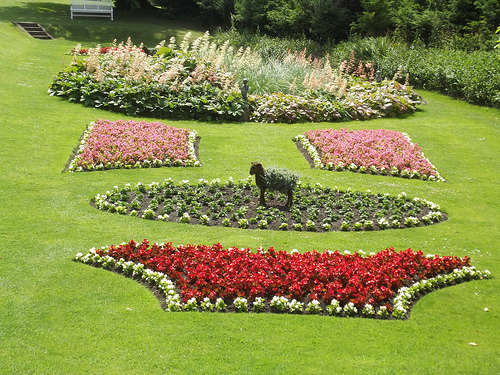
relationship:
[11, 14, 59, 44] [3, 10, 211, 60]
stairs on hill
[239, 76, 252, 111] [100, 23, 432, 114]
statue in plants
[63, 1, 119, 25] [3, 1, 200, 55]
bench on hill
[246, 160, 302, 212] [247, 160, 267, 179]
animal has head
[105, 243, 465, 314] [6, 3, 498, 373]
flower in ground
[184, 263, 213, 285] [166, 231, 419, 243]
flowers in ground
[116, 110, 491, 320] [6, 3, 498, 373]
flowers in ground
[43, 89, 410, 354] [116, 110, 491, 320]
grass around flowers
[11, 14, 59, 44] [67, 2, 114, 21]
stairs lead to bench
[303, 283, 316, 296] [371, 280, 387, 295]
flower next to flower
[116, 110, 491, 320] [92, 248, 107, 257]
flowers next to flower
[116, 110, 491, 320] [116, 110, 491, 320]
flowers next to flowers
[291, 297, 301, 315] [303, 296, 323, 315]
flower next to flower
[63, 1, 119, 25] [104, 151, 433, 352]
bench in back